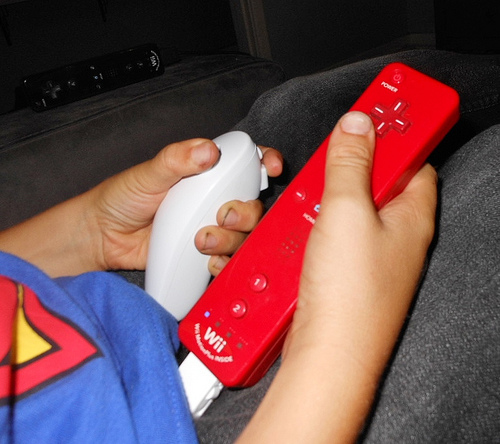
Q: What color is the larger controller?
A: Red.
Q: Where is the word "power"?
A: Top of red controller.